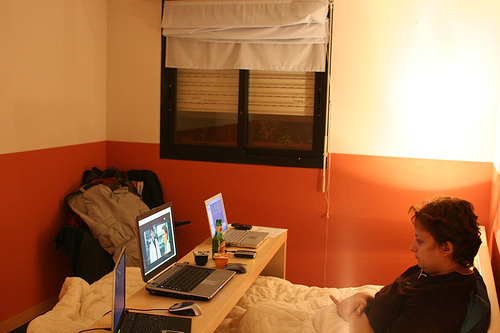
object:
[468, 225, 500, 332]
headboard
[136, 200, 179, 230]
top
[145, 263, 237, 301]
keyboard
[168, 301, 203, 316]
mouse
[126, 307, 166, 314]
wire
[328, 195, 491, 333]
person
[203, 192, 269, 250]
computer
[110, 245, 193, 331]
computer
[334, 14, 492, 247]
paint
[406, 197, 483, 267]
hair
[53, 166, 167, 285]
bag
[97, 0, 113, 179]
corner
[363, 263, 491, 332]
shirt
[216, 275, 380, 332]
blanket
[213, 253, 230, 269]
cup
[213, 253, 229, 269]
jello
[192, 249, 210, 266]
jello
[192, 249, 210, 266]
cup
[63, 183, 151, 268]
pants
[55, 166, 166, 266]
laundry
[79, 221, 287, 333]
table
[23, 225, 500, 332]
bed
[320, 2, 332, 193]
cord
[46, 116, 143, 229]
clothes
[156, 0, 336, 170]
window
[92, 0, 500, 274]
wall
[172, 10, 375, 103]
shade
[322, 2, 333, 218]
cords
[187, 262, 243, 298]
pad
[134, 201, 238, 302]
computer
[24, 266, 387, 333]
bedspread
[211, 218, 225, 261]
bottle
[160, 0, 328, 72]
curtain